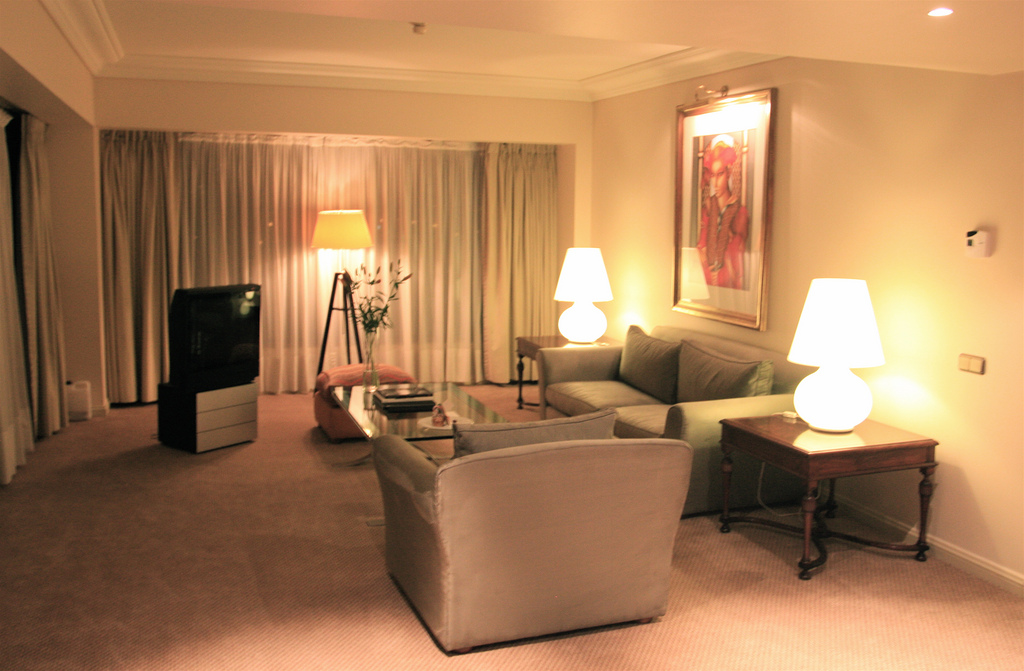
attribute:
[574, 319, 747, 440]
sofa — small, gray, brown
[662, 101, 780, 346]
picture — hanging, big, bright, red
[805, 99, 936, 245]
wall — white, brown, clean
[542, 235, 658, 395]
light — bright, on, shining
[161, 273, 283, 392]
tv — small, off, black, older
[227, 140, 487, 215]
curtains — closed, white, brown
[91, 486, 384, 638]
floor — beige, clean, neat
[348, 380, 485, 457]
table — glass, clear